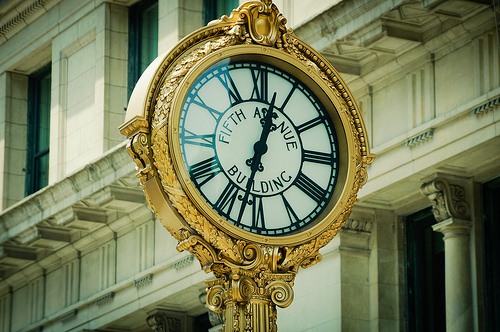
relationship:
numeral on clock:
[189, 90, 226, 123] [122, 2, 377, 327]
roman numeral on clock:
[184, 156, 221, 187] [119, 7, 375, 280]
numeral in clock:
[292, 171, 326, 204] [162, 29, 363, 254]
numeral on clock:
[245, 187, 271, 234] [94, 8, 408, 265]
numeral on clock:
[296, 174, 331, 201] [122, 2, 377, 327]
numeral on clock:
[292, 171, 326, 204] [153, 42, 352, 260]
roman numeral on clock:
[303, 148, 334, 168] [122, 2, 377, 327]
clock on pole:
[138, 47, 364, 244] [205, 270, 297, 326]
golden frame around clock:
[118, 1, 371, 273] [179, 59, 337, 235]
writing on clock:
[219, 106, 297, 191] [179, 59, 337, 235]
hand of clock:
[239, 81, 330, 211] [189, 55, 359, 240]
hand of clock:
[237, 158, 257, 233] [182, 60, 357, 247]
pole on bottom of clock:
[205, 265, 292, 330] [179, 59, 337, 235]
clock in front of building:
[118, 0, 376, 332] [7, 18, 437, 274]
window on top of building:
[22, 61, 52, 196] [0, 2, 497, 329]